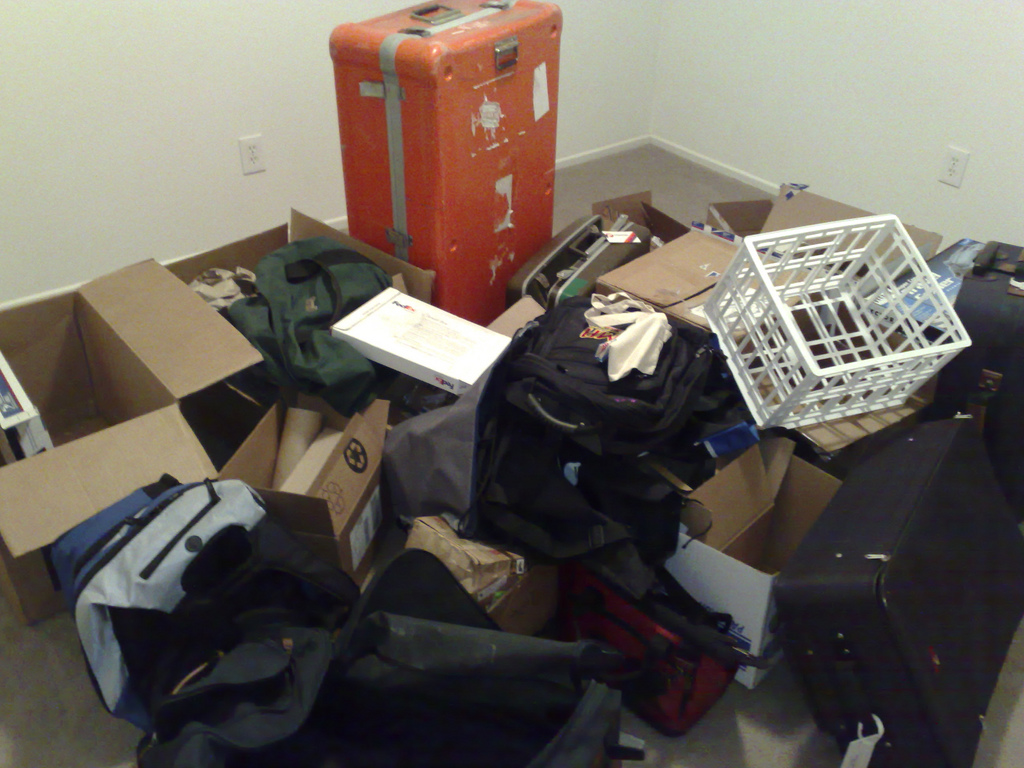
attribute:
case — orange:
[316, 21, 666, 285]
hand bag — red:
[567, 572, 738, 732]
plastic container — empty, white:
[700, 209, 971, 430]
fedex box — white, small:
[325, 289, 518, 404]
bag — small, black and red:
[571, 557, 747, 733]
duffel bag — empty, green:
[234, 235, 407, 408]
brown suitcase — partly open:
[506, 213, 641, 313]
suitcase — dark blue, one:
[951, 239, 993, 430]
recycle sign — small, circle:
[342, 438, 369, 477]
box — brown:
[223, 390, 392, 576]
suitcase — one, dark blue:
[772, 414, 991, 764]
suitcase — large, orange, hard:
[331, 2, 561, 305]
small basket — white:
[707, 217, 975, 432]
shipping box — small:
[335, 280, 517, 399]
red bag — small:
[562, 565, 751, 738]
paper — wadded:
[580, 282, 676, 382]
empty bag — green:
[219, 241, 379, 401]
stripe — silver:
[380, 214, 428, 277]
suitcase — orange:
[335, 35, 578, 277]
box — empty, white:
[732, 236, 927, 416]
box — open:
[23, 303, 207, 444]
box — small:
[244, 411, 396, 591]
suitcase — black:
[818, 452, 993, 710]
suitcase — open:
[514, 219, 610, 297]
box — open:
[691, 450, 797, 615]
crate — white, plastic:
[747, 230, 966, 418]